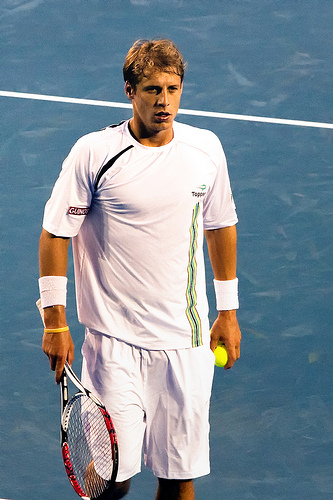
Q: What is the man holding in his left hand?
A: A ball.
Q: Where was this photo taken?
A: On a tennis court.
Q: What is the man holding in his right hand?
A: A tennis racket.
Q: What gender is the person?
A: Male.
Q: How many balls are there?
A: One.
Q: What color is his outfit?
A: White.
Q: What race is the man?
A: White.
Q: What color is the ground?
A: Blue.